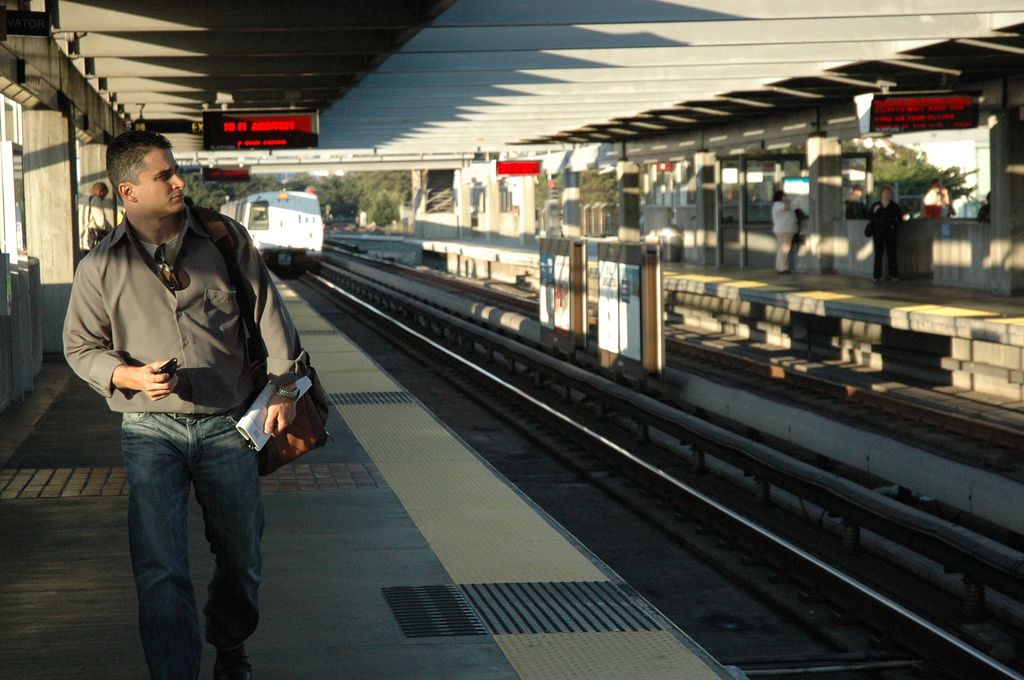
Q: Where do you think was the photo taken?
A: It was taken at the train station.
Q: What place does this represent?
A: It represents the train station.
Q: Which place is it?
A: It is a train station.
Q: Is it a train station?
A: Yes, it is a train station.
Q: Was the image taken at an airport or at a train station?
A: It was taken at a train station.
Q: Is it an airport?
A: No, it is a train station.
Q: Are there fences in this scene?
A: No, there are no fences.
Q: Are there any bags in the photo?
A: Yes, there is a bag.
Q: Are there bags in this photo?
A: Yes, there is a bag.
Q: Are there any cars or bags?
A: Yes, there is a bag.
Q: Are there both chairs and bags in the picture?
A: No, there is a bag but no chairs.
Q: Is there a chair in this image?
A: No, there are no chairs.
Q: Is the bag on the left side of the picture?
A: Yes, the bag is on the left of the image.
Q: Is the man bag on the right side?
A: No, the bag is on the left of the image.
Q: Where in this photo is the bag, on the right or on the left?
A: The bag is on the left of the image.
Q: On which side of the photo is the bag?
A: The bag is on the left of the image.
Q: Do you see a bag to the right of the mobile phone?
A: Yes, there is a bag to the right of the mobile phone.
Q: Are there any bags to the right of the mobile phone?
A: Yes, there is a bag to the right of the mobile phone.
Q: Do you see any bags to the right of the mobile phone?
A: Yes, there is a bag to the right of the mobile phone.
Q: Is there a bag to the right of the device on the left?
A: Yes, there is a bag to the right of the mobile phone.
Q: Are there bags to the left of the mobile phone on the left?
A: No, the bag is to the right of the mobile phone.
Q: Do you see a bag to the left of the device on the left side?
A: No, the bag is to the right of the mobile phone.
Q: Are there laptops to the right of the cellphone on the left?
A: No, there is a bag to the right of the cellphone.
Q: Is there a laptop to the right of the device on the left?
A: No, there is a bag to the right of the cellphone.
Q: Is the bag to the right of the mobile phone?
A: Yes, the bag is to the right of the mobile phone.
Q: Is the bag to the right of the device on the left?
A: Yes, the bag is to the right of the mobile phone.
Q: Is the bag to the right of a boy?
A: No, the bag is to the right of the mobile phone.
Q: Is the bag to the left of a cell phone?
A: No, the bag is to the right of a cell phone.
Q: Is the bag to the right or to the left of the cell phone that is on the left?
A: The bag is to the right of the mobile phone.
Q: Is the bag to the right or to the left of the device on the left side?
A: The bag is to the right of the mobile phone.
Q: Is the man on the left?
A: Yes, the man is on the left of the image.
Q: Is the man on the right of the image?
A: No, the man is on the left of the image.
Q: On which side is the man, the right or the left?
A: The man is on the left of the image.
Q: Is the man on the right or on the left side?
A: The man is on the left of the image.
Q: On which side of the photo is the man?
A: The man is on the left of the image.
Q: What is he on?
A: The man is on the platform.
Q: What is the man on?
A: The man is on the platform.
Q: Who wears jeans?
A: The man wears jeans.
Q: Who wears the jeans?
A: The man wears jeans.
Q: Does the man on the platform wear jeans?
A: Yes, the man wears jeans.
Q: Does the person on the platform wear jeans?
A: Yes, the man wears jeans.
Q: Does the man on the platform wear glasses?
A: No, the man wears jeans.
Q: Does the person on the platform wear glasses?
A: No, the man wears jeans.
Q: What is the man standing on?
A: The man is standing on the platform.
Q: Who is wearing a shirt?
A: The man is wearing a shirt.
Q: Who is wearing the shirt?
A: The man is wearing a shirt.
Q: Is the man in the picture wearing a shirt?
A: Yes, the man is wearing a shirt.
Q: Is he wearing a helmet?
A: No, the man is wearing a shirt.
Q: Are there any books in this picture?
A: No, there are no books.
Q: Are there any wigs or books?
A: No, there are no books or wigs.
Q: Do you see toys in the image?
A: No, there are no toys.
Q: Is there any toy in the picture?
A: No, there are no toys.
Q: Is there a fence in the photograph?
A: No, there are no fences.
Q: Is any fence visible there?
A: No, there are no fences.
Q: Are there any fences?
A: No, there are no fences.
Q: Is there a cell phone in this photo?
A: Yes, there is a cell phone.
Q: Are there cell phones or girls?
A: Yes, there is a cell phone.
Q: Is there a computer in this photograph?
A: No, there are no computers.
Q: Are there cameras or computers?
A: No, there are no computers or cameras.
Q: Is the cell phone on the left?
A: Yes, the cell phone is on the left of the image.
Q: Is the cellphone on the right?
A: No, the cellphone is on the left of the image.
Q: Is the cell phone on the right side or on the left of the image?
A: The cell phone is on the left of the image.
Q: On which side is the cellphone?
A: The cellphone is on the left of the image.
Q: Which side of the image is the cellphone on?
A: The cellphone is on the left of the image.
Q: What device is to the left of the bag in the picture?
A: The device is a cell phone.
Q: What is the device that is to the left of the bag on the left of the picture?
A: The device is a cell phone.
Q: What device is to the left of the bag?
A: The device is a cell phone.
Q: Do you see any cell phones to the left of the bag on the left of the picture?
A: Yes, there is a cell phone to the left of the bag.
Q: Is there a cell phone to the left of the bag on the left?
A: Yes, there is a cell phone to the left of the bag.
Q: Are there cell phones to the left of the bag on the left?
A: Yes, there is a cell phone to the left of the bag.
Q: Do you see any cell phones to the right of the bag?
A: No, the cell phone is to the left of the bag.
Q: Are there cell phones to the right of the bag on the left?
A: No, the cell phone is to the left of the bag.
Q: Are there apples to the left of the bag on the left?
A: No, there is a cell phone to the left of the bag.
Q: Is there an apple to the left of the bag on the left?
A: No, there is a cell phone to the left of the bag.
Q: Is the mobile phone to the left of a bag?
A: Yes, the mobile phone is to the left of a bag.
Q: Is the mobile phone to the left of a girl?
A: No, the mobile phone is to the left of a bag.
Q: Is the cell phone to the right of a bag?
A: No, the cell phone is to the left of a bag.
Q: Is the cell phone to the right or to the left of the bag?
A: The cell phone is to the left of the bag.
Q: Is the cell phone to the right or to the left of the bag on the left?
A: The cell phone is to the left of the bag.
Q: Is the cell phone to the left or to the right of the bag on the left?
A: The cell phone is to the left of the bag.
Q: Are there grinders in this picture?
A: No, there are no grinders.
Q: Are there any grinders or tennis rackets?
A: No, there are no grinders or tennis rackets.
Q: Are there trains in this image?
A: Yes, there is a train.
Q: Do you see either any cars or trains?
A: Yes, there is a train.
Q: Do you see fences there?
A: No, there are no fences.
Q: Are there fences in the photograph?
A: No, there are no fences.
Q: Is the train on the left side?
A: Yes, the train is on the left of the image.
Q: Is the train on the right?
A: No, the train is on the left of the image.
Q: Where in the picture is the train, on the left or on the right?
A: The train is on the left of the image.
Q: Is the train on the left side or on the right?
A: The train is on the left of the image.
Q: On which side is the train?
A: The train is on the left of the image.